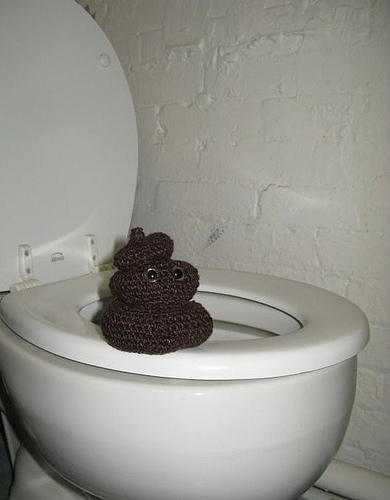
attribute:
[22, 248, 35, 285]
bolts —  two,  silver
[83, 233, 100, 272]
bolts —  silver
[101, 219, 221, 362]
poop —  Brown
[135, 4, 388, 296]
wall —  of toilet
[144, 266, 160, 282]
eye — small, black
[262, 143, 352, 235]
wall — white 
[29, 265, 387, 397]
lid —  White,  toilet's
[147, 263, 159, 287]
eye —  doll's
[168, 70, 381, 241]
wall — white 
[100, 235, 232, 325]
black frog — black , urgly 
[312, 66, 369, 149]
wall — white 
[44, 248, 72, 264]
toilet logo —  toilet's,  Silver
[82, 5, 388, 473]
wall — white 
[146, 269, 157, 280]
eye —  Two,  black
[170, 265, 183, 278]
eye —  black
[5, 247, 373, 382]
lid —  White,  toilet bowl's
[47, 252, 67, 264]
logo —  Silver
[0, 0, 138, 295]
toilet lid —  White ,  toilet's,   toilet's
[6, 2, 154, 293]
toilet cover —  White,  toilet bowl's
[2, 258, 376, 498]
toilet bowl — White 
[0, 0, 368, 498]
toilet — White,   bathroom's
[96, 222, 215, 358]
fake poop — fake 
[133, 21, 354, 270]
cracks —  White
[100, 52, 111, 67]
bolt —  One,  white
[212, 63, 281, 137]
cracks — white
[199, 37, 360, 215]
toilet wall — white 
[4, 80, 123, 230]
seat —  toilet's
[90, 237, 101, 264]
bolt — silver